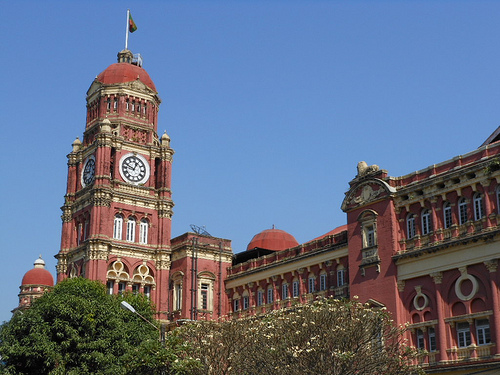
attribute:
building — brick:
[17, 9, 498, 373]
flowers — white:
[150, 287, 427, 369]